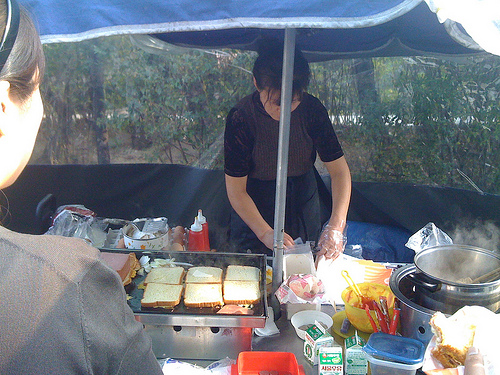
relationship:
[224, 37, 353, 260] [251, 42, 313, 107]
woman has hair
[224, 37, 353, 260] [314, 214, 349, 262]
woman wearing glove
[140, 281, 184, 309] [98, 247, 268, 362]
sandwich on grill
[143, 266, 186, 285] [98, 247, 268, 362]
sandwich on grill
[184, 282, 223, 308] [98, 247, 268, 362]
sandwich on grill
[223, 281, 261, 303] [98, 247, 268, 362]
sandwich on grill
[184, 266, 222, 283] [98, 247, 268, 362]
sandwich on grill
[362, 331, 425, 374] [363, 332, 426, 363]
tupperware has lid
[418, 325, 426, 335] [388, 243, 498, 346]
hole in pot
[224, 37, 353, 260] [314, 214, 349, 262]
woman has glove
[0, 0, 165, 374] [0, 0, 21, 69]
woman has hairband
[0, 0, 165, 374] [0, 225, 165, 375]
woman has shirt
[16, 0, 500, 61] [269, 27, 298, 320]
tent has pole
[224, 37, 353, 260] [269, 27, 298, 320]
woman behind pole